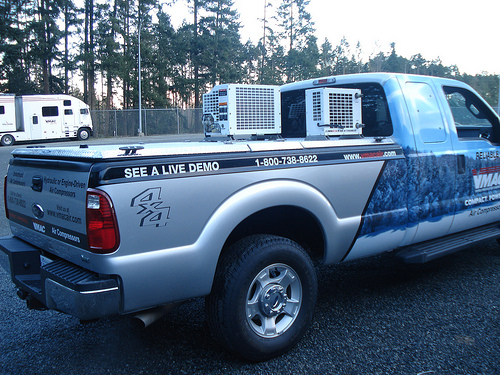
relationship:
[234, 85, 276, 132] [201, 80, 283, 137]
holes on machine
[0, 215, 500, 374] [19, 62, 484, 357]
gravel beneath truck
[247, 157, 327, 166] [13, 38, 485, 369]
numbers side of truck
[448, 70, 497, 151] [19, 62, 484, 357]
window of truck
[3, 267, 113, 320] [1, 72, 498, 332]
bumper of truck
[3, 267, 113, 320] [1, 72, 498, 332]
bumper back of truck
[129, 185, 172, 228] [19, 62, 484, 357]
symbol on truck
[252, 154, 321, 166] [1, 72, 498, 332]
phone number on side of truck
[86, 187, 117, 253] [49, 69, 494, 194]
tail light on back of truck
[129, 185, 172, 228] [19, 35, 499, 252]
symbol painted onto truck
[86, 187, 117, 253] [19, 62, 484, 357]
tail light on back of truck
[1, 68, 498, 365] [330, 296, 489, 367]
truck parked on top of gravel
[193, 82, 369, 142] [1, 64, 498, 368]
machines inside of truck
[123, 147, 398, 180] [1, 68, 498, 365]
advertisements on truck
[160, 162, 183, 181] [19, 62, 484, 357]
word on truck